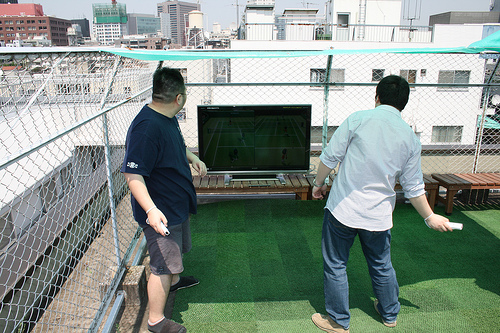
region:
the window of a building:
[3, 20, 9, 25]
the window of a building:
[9, 19, 13, 25]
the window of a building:
[16, 16, 25, 26]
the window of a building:
[37, 20, 46, 27]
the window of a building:
[6, 27, 16, 29]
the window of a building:
[21, 24, 30, 31]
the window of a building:
[37, 30, 49, 37]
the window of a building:
[20, 33, 30, 36]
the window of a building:
[5, 30, 13, 37]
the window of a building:
[23, 25, 26, 27]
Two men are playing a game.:
[97, 28, 463, 332]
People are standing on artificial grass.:
[152, 210, 448, 331]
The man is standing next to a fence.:
[34, 39, 229, 331]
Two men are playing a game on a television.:
[119, 56, 440, 331]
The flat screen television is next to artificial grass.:
[191, 93, 321, 266]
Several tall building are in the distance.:
[10, 0, 331, 40]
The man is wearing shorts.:
[135, 205, 210, 325]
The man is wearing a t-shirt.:
[120, 102, 215, 237]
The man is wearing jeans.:
[309, 198, 425, 331]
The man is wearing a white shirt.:
[303, 100, 441, 233]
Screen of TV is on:
[190, 96, 315, 188]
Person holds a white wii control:
[293, 65, 473, 332]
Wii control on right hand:
[396, 137, 476, 248]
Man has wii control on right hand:
[108, 61, 221, 331]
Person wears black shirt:
[111, 58, 208, 328]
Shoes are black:
[110, 270, 211, 331]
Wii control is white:
[417, 213, 472, 233]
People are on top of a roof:
[0, 23, 499, 321]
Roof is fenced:
[7, 37, 493, 330]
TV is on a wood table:
[183, 97, 315, 210]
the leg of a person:
[138, 212, 184, 329]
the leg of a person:
[172, 240, 200, 299]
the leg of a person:
[313, 212, 356, 327]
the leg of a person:
[371, 202, 408, 329]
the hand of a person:
[115, 151, 172, 254]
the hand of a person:
[181, 143, 213, 180]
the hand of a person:
[306, 132, 354, 198]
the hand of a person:
[402, 156, 464, 243]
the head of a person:
[146, 63, 184, 113]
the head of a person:
[370, 65, 412, 115]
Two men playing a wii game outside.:
[41, 30, 488, 320]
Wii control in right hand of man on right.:
[421, 202, 476, 240]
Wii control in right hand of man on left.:
[132, 196, 177, 243]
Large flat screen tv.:
[189, 87, 327, 194]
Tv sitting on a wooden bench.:
[196, 96, 327, 205]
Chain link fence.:
[9, 56, 129, 327]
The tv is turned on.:
[196, 98, 319, 180]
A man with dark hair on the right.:
[308, 70, 461, 315]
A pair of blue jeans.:
[305, 198, 425, 324]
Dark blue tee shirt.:
[122, 93, 207, 239]